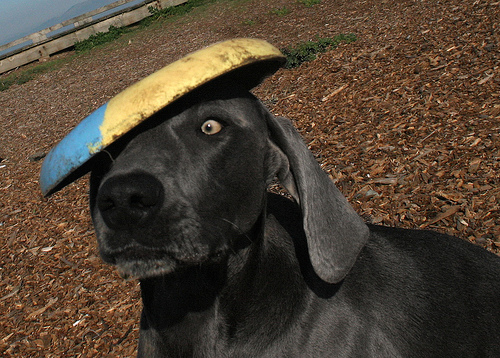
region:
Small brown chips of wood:
[446, 158, 498, 210]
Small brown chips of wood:
[443, 206, 496, 245]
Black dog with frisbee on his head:
[37, 46, 499, 351]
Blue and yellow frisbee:
[20, 78, 154, 171]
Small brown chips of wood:
[322, 124, 393, 196]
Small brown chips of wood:
[385, 112, 462, 165]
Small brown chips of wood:
[400, 61, 479, 104]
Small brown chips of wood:
[296, 90, 388, 141]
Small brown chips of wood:
[48, 300, 136, 351]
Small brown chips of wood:
[17, 227, 104, 304]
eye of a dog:
[197, 114, 226, 139]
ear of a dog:
[260, 105, 375, 293]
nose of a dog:
[90, 168, 169, 235]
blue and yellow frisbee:
[23, 22, 293, 218]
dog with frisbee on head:
[17, 35, 498, 356]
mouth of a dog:
[102, 228, 181, 278]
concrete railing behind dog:
[0, 0, 141, 79]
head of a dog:
[13, 28, 382, 300]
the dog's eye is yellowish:
[195, 115, 227, 137]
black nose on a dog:
[93, 170, 158, 236]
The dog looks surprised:
[32, 23, 492, 350]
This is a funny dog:
[39, 25, 387, 293]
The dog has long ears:
[262, 108, 389, 300]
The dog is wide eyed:
[164, 103, 248, 156]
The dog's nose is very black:
[93, 164, 176, 235]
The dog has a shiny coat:
[268, 180, 483, 349]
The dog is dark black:
[52, 39, 496, 346]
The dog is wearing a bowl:
[25, 25, 319, 192]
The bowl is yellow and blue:
[28, 26, 310, 203]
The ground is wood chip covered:
[319, 41, 480, 229]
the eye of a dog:
[189, 100, 245, 165]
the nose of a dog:
[91, 169, 192, 239]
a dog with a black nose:
[81, 159, 200, 270]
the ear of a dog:
[246, 91, 403, 304]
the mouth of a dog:
[91, 218, 216, 283]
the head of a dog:
[79, 58, 369, 311]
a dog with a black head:
[51, 41, 374, 306]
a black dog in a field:
[36, 55, 441, 332]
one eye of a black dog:
[173, 87, 270, 162]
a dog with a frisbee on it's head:
[41, 30, 371, 272]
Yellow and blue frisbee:
[14, 54, 313, 131]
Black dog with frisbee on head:
[50, 47, 484, 357]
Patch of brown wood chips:
[434, 174, 488, 241]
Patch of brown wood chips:
[390, 166, 477, 256]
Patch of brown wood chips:
[350, 120, 397, 173]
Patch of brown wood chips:
[403, 108, 452, 165]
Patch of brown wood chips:
[439, 101, 496, 162]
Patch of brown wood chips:
[41, 289, 96, 341]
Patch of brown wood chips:
[90, 274, 140, 354]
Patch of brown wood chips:
[3, 202, 70, 254]